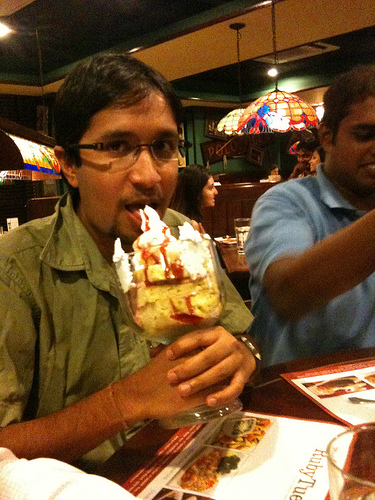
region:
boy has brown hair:
[71, 58, 168, 158]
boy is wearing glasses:
[55, 136, 176, 176]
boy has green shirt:
[11, 206, 196, 416]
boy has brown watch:
[228, 328, 265, 390]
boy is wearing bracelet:
[83, 371, 138, 436]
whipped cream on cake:
[102, 199, 211, 286]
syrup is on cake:
[122, 222, 207, 282]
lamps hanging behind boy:
[212, 52, 327, 163]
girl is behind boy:
[173, 159, 221, 232]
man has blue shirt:
[255, 154, 372, 354]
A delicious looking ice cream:
[115, 214, 194, 285]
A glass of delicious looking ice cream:
[110, 255, 241, 423]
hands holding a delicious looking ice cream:
[155, 345, 238, 415]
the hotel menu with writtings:
[132, 412, 331, 498]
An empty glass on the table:
[327, 444, 373, 489]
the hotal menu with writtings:
[281, 371, 373, 417]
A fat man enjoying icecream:
[45, 38, 241, 396]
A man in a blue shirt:
[264, 182, 370, 351]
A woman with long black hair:
[181, 161, 224, 219]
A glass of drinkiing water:
[229, 218, 253, 256]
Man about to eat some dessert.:
[102, 205, 232, 341]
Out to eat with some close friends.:
[39, 44, 193, 251]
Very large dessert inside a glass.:
[109, 205, 238, 340]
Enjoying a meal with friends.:
[310, 60, 373, 195]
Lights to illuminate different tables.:
[236, 87, 317, 136]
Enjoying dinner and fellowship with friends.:
[173, 164, 218, 215]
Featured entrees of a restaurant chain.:
[177, 413, 278, 494]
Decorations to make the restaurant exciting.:
[194, 110, 284, 167]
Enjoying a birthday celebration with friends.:
[40, 50, 228, 362]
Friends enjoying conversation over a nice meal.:
[278, 132, 328, 190]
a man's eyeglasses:
[66, 132, 197, 165]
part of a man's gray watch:
[229, 326, 261, 381]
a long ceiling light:
[233, 0, 323, 134]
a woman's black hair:
[174, 165, 212, 223]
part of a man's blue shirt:
[248, 163, 373, 367]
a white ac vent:
[259, 40, 336, 66]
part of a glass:
[231, 217, 252, 255]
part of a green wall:
[0, 0, 256, 88]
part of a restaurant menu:
[120, 406, 357, 499]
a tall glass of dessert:
[106, 245, 243, 426]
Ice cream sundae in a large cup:
[105, 201, 233, 339]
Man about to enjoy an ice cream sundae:
[47, 49, 186, 238]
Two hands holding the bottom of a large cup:
[120, 320, 258, 411]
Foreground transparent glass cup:
[318, 419, 373, 499]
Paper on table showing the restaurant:
[120, 403, 358, 497]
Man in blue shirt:
[234, 63, 372, 353]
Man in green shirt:
[0, 55, 252, 475]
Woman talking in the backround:
[167, 161, 218, 226]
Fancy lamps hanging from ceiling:
[216, 88, 321, 133]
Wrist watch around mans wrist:
[222, 332, 263, 385]